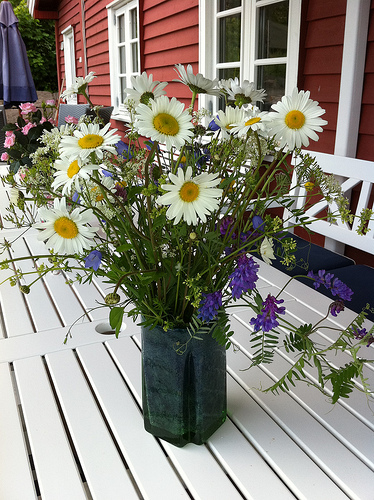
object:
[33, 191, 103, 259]
flower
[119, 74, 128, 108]
window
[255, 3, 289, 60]
window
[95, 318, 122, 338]
hole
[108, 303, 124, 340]
leaf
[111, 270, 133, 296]
stem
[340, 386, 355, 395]
leaf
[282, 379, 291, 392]
leaf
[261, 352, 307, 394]
stem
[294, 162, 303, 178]
leaf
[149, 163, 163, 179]
leaf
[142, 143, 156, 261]
stem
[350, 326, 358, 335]
leaf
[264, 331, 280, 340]
leaf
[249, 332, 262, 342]
leaf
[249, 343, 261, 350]
leaf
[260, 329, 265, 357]
stem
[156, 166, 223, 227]
daisies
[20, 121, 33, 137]
flowers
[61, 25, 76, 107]
door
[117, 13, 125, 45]
window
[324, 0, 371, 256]
downspout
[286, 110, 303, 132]
centers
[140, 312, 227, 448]
vase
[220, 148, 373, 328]
bench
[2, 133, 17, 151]
roses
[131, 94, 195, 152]
flowers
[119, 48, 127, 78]
windows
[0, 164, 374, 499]
table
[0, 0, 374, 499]
house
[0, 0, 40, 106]
umbrella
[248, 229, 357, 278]
cushion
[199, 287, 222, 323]
flower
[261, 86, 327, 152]
flower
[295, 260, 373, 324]
cushion